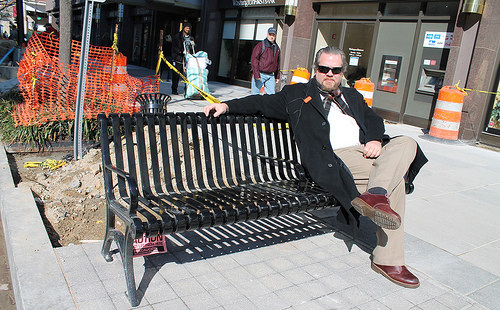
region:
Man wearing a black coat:
[207, 45, 440, 290]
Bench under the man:
[87, 103, 409, 308]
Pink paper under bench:
[119, 219, 173, 267]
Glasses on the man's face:
[311, 59, 347, 81]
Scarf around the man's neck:
[313, 81, 358, 121]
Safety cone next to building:
[416, 81, 474, 151]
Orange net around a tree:
[8, 28, 131, 130]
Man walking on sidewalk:
[245, 21, 283, 101]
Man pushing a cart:
[156, 21, 213, 104]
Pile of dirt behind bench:
[22, 114, 319, 245]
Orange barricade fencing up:
[15, 37, 158, 125]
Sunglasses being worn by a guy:
[313, 65, 345, 74]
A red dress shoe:
[367, 258, 417, 286]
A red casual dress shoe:
[349, 190, 401, 228]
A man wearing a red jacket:
[250, 28, 282, 94]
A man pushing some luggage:
[170, 20, 210, 99]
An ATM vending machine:
[377, 51, 399, 92]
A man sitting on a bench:
[204, 43, 426, 286]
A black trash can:
[134, 92, 171, 112]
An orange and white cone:
[428, 85, 462, 143]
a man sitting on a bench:
[93, 45, 431, 301]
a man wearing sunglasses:
[310, 42, 350, 105]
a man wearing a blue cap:
[261, 23, 279, 44]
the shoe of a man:
[348, 186, 401, 234]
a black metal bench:
[89, 108, 322, 307]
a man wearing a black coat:
[203, 52, 426, 194]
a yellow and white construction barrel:
[418, 77, 474, 150]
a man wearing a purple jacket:
[250, 23, 287, 75]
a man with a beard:
[310, 34, 349, 104]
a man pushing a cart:
[163, 22, 212, 97]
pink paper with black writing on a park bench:
[133, 233, 166, 256]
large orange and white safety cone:
[418, 85, 466, 145]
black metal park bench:
[96, 110, 340, 304]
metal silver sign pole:
[73, 0, 93, 157]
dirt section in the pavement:
[8, 126, 254, 246]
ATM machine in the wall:
[414, 46, 448, 94]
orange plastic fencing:
[13, 30, 160, 124]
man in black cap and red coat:
[250, 27, 280, 94]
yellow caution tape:
[155, 51, 219, 103]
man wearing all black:
[170, 20, 197, 93]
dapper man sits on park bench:
[184, 36, 426, 293]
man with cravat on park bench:
[197, 44, 427, 286]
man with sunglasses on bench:
[200, 41, 427, 283]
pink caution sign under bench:
[117, 222, 177, 265]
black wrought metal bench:
[88, 102, 310, 294]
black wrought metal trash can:
[130, 89, 174, 116]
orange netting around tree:
[14, 31, 162, 121]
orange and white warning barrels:
[417, 78, 477, 143]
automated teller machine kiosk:
[408, 22, 452, 137]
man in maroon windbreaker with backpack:
[245, 17, 289, 94]